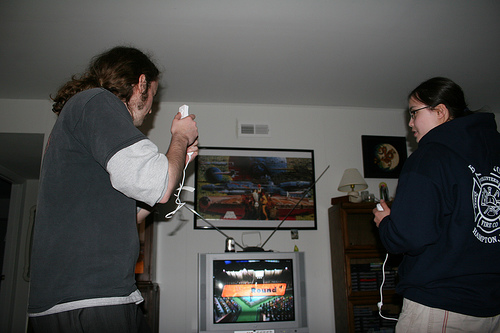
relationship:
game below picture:
[213, 259, 295, 324] [195, 146, 317, 230]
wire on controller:
[164, 155, 192, 219] [178, 104, 189, 119]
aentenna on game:
[257, 164, 332, 249] [213, 259, 295, 324]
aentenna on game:
[184, 203, 245, 248] [213, 259, 295, 324]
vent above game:
[236, 122, 273, 138] [213, 259, 295, 324]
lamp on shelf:
[338, 169, 368, 202] [328, 202, 378, 211]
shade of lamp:
[338, 171, 370, 192] [338, 169, 368, 202]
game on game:
[213, 260, 292, 321] [213, 259, 295, 324]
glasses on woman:
[409, 105, 430, 120] [371, 75, 500, 332]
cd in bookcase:
[369, 261, 385, 265] [327, 202, 404, 333]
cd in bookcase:
[371, 269, 387, 270] [327, 202, 404, 333]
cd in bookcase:
[371, 262, 384, 267] [327, 202, 404, 333]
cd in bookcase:
[360, 278, 377, 282] [327, 202, 404, 333]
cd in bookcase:
[360, 272, 377, 276] [327, 202, 404, 333]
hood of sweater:
[417, 113, 495, 174] [375, 113, 500, 318]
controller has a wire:
[178, 104, 189, 119] [164, 155, 192, 219]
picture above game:
[195, 146, 317, 230] [213, 259, 295, 324]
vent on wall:
[236, 122, 273, 138] [156, 104, 413, 204]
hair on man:
[51, 44, 160, 116] [26, 47, 198, 333]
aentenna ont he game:
[257, 164, 332, 249] [213, 259, 295, 324]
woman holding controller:
[371, 75, 500, 332] [376, 201, 383, 213]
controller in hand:
[178, 104, 189, 119] [170, 113, 199, 141]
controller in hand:
[376, 201, 383, 213] [373, 199, 391, 232]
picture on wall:
[195, 146, 317, 230] [156, 104, 413, 204]